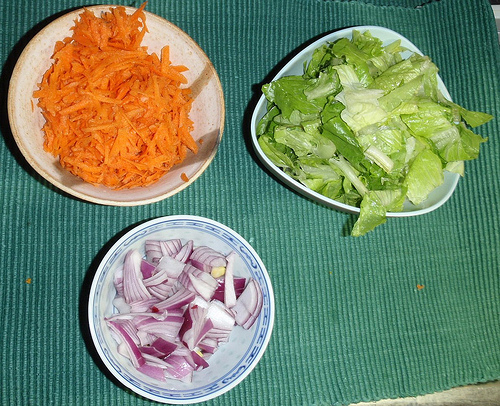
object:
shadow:
[51, 159, 89, 190]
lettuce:
[349, 181, 409, 239]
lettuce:
[401, 148, 445, 207]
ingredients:
[29, 0, 205, 191]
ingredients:
[254, 28, 495, 239]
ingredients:
[103, 239, 263, 385]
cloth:
[0, 0, 499, 406]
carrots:
[57, 99, 87, 116]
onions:
[174, 243, 189, 262]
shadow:
[167, 127, 220, 172]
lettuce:
[433, 88, 496, 130]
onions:
[190, 350, 210, 369]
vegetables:
[114, 73, 137, 100]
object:
[223, 251, 237, 310]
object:
[272, 118, 336, 160]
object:
[79, 122, 114, 133]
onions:
[140, 258, 156, 279]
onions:
[112, 296, 133, 315]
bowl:
[6, 3, 225, 207]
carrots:
[160, 44, 170, 74]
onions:
[205, 302, 236, 331]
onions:
[155, 255, 188, 279]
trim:
[244, 345, 260, 364]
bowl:
[249, 25, 464, 217]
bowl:
[87, 214, 276, 405]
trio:
[28, 0, 497, 384]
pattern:
[30, 98, 35, 112]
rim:
[87, 214, 275, 405]